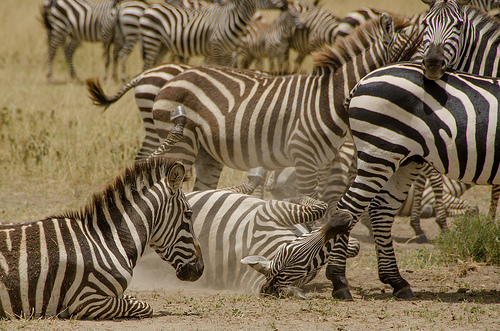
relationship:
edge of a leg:
[316, 264, 366, 316] [316, 166, 456, 329]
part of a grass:
[394, 210, 496, 327] [436, 209, 499, 265]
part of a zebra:
[78, 271, 150, 323] [182, 180, 390, 297]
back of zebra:
[204, 226, 260, 273] [151, 173, 361, 297]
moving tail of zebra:
[70, 64, 128, 114] [89, 60, 206, 165]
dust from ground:
[158, 241, 253, 294] [187, 279, 497, 329]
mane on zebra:
[52, 156, 182, 221] [2, 154, 206, 321]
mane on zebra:
[310, 10, 410, 70] [160, 10, 421, 229]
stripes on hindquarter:
[349, 60, 499, 185] [332, 52, 462, 182]